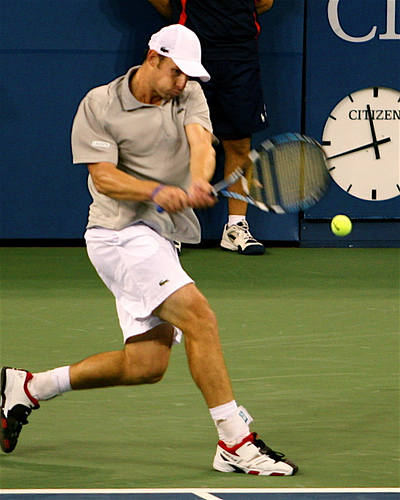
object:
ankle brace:
[214, 405, 254, 443]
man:
[0, 20, 299, 478]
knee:
[185, 304, 219, 342]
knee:
[124, 348, 171, 386]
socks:
[208, 399, 253, 449]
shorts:
[85, 222, 197, 346]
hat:
[148, 24, 209, 84]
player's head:
[146, 24, 191, 100]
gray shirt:
[71, 65, 214, 244]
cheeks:
[158, 76, 173, 93]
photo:
[0, 0, 400, 500]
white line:
[0, 486, 400, 495]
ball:
[330, 215, 352, 236]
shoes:
[212, 431, 299, 477]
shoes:
[0, 367, 41, 453]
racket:
[157, 132, 330, 214]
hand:
[187, 179, 216, 207]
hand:
[153, 185, 188, 211]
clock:
[321, 84, 400, 202]